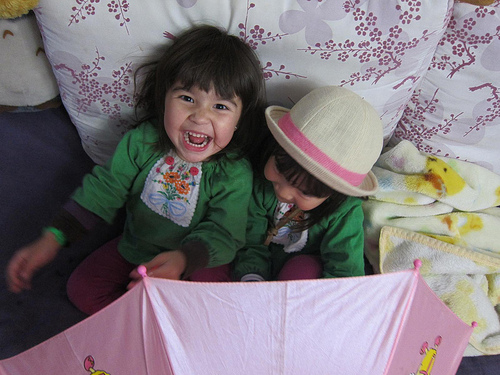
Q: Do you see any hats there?
A: Yes, there is a hat.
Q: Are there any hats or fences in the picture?
A: Yes, there is a hat.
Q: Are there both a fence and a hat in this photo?
A: No, there is a hat but no fences.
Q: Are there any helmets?
A: No, there are no helmets.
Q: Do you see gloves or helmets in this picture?
A: No, there are no helmets or gloves.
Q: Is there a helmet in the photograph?
A: No, there are no helmets.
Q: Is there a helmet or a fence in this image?
A: No, there are no helmets or fences.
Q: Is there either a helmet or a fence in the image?
A: No, there are no fences or helmets.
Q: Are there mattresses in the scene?
A: No, there are no mattresses.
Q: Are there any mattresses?
A: No, there are no mattresses.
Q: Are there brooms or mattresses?
A: No, there are no mattresses or brooms.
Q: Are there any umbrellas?
A: Yes, there is an umbrella.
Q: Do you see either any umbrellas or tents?
A: Yes, there is an umbrella.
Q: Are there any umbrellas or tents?
A: Yes, there is an umbrella.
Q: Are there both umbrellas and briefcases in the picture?
A: No, there is an umbrella but no briefcases.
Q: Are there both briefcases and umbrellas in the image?
A: No, there is an umbrella but no briefcases.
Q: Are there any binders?
A: No, there are no binders.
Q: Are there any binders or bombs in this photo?
A: No, there are no binders or bombs.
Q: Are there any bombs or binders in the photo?
A: No, there are no binders or bombs.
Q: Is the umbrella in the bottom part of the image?
A: Yes, the umbrella is in the bottom of the image.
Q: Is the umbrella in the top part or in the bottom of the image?
A: The umbrella is in the bottom of the image.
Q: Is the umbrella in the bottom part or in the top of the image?
A: The umbrella is in the bottom of the image.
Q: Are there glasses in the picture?
A: No, there are no glasses.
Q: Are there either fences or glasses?
A: No, there are no glasses or fences.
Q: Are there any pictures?
A: No, there are no pictures.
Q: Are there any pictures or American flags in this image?
A: No, there are no pictures or American flags.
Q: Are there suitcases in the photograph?
A: No, there are no suitcases.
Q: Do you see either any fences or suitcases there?
A: No, there are no suitcases or fences.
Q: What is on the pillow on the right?
A: The flowers are on the pillow.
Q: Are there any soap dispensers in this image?
A: No, there are no soap dispensers.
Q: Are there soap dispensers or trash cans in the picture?
A: No, there are no soap dispensers or trash cans.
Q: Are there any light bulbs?
A: No, there are no light bulbs.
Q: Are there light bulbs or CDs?
A: No, there are no light bulbs or cds.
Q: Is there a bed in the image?
A: Yes, there is a bed.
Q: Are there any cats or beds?
A: Yes, there is a bed.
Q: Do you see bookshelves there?
A: No, there are no bookshelves.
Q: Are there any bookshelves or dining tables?
A: No, there are no bookshelves or dining tables.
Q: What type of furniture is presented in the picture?
A: The furniture is a bed.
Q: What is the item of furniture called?
A: The piece of furniture is a bed.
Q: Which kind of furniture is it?
A: The piece of furniture is a bed.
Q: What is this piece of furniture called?
A: This is a bed.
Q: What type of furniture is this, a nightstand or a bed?
A: This is a bed.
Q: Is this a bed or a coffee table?
A: This is a bed.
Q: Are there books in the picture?
A: No, there are no books.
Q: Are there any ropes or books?
A: No, there are no books or ropes.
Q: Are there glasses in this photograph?
A: No, there are no glasses.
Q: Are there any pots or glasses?
A: No, there are no glasses or pots.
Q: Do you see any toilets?
A: No, there are no toilets.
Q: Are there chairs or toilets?
A: No, there are no toilets or chairs.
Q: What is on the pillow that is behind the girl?
A: The flowers are on the pillow.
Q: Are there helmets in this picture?
A: No, there are no helmets.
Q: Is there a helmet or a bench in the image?
A: No, there are no helmets or benches.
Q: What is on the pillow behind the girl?
A: The flowers are on the pillow.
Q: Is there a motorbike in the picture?
A: No, there are no motorcycles.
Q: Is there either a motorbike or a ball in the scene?
A: No, there are no motorcycles or balls.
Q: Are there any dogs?
A: No, there are no dogs.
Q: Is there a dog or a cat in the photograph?
A: No, there are no dogs or cats.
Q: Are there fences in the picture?
A: No, there are no fences.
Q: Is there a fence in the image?
A: No, there are no fences.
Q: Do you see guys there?
A: No, there are no guys.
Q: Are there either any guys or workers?
A: No, there are no guys or workers.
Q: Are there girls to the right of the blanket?
A: No, the girl is to the left of the blanket.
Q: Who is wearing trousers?
A: The girl is wearing trousers.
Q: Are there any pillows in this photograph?
A: Yes, there is a pillow.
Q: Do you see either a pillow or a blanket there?
A: Yes, there is a pillow.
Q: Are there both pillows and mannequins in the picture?
A: No, there is a pillow but no mannequins.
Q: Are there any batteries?
A: No, there are no batteries.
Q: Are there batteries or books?
A: No, there are no batteries or books.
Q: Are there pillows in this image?
A: Yes, there is a pillow.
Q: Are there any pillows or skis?
A: Yes, there is a pillow.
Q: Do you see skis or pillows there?
A: Yes, there is a pillow.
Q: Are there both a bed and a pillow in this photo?
A: Yes, there are both a pillow and a bed.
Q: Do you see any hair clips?
A: No, there are no hair clips.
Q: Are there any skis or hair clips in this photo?
A: No, there are no hair clips or skis.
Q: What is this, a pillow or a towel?
A: This is a pillow.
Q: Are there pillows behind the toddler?
A: Yes, there is a pillow behind the toddler.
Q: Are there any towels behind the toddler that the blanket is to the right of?
A: No, there is a pillow behind the toddler.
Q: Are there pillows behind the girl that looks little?
A: Yes, there is a pillow behind the girl.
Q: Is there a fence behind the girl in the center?
A: No, there is a pillow behind the girl.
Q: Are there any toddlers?
A: Yes, there is a toddler.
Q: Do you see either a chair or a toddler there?
A: Yes, there is a toddler.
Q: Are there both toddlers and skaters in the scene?
A: No, there is a toddler but no skaters.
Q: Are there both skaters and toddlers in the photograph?
A: No, there is a toddler but no skaters.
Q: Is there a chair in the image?
A: No, there are no chairs.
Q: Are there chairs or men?
A: No, there are no chairs or men.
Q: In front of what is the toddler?
A: The toddler is in front of the pillow.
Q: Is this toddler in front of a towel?
A: No, the toddler is in front of the pillow.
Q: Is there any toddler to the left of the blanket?
A: Yes, there is a toddler to the left of the blanket.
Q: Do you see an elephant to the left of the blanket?
A: No, there is a toddler to the left of the blanket.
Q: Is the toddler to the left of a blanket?
A: Yes, the toddler is to the left of a blanket.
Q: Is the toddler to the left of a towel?
A: No, the toddler is to the left of a blanket.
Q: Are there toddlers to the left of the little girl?
A: Yes, there is a toddler to the left of the girl.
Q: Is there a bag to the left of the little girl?
A: No, there is a toddler to the left of the girl.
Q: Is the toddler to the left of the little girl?
A: Yes, the toddler is to the left of the girl.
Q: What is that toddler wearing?
A: The toddler is wearing a shirt.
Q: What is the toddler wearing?
A: The toddler is wearing a shirt.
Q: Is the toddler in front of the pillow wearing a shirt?
A: Yes, the toddler is wearing a shirt.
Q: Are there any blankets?
A: Yes, there is a blanket.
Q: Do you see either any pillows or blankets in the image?
A: Yes, there is a blanket.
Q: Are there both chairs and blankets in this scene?
A: No, there is a blanket but no chairs.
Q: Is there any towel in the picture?
A: No, there are no towels.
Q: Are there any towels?
A: No, there are no towels.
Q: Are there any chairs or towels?
A: No, there are no towels or chairs.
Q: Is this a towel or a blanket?
A: This is a blanket.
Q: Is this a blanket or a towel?
A: This is a blanket.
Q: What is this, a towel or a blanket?
A: This is a blanket.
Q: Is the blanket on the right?
A: Yes, the blanket is on the right of the image.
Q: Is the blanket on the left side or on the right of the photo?
A: The blanket is on the right of the image.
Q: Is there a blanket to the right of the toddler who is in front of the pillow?
A: Yes, there is a blanket to the right of the toddler.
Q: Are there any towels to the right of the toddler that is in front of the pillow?
A: No, there is a blanket to the right of the toddler.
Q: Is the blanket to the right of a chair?
A: No, the blanket is to the right of a toddler.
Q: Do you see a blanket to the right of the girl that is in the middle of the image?
A: Yes, there is a blanket to the right of the girl.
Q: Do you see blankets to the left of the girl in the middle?
A: No, the blanket is to the right of the girl.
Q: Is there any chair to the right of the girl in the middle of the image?
A: No, there is a blanket to the right of the girl.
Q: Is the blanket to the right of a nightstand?
A: No, the blanket is to the right of a girl.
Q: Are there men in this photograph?
A: No, there are no men.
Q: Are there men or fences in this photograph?
A: No, there are no men or fences.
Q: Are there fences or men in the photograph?
A: No, there are no men or fences.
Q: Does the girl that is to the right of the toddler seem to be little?
A: Yes, the girl is little.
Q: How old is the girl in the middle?
A: The girl is little.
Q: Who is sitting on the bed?
A: The girl is sitting on the bed.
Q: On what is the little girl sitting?
A: The girl is sitting on the bed.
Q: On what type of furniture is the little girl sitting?
A: The girl is sitting on the bed.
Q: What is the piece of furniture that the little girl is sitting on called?
A: The piece of furniture is a bed.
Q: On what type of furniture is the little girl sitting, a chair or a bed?
A: The girl is sitting on a bed.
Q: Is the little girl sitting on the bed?
A: Yes, the girl is sitting on the bed.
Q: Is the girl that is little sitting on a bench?
A: No, the girl is sitting on the bed.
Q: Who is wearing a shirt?
A: The girl is wearing a shirt.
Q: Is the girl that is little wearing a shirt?
A: Yes, the girl is wearing a shirt.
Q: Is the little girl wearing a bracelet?
A: No, the girl is wearing a shirt.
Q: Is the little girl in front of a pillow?
A: Yes, the girl is in front of a pillow.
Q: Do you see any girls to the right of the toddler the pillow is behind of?
A: Yes, there is a girl to the right of the toddler.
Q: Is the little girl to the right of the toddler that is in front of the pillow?
A: Yes, the girl is to the right of the toddler.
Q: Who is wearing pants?
A: The girl is wearing pants.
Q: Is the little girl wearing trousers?
A: Yes, the girl is wearing trousers.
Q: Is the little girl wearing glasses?
A: No, the girl is wearing trousers.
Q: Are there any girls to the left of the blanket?
A: Yes, there is a girl to the left of the blanket.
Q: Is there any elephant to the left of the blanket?
A: No, there is a girl to the left of the blanket.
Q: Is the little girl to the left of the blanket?
A: Yes, the girl is to the left of the blanket.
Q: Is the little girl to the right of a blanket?
A: No, the girl is to the left of a blanket.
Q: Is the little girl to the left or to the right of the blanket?
A: The girl is to the left of the blanket.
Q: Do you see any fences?
A: No, there are no fences.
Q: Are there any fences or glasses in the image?
A: No, there are no fences or glasses.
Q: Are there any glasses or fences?
A: No, there are no fences or glasses.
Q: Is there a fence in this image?
A: No, there are no fences.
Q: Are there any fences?
A: No, there are no fences.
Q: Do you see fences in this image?
A: No, there are no fences.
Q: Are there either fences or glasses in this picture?
A: No, there are no fences or glasses.